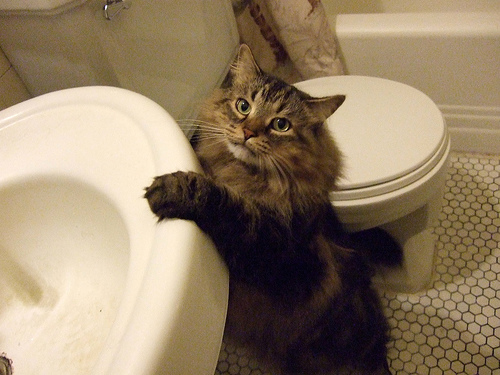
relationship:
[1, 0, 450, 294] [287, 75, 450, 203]
toilet has seat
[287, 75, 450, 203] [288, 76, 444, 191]
seat has cover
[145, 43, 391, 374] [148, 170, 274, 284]
cat has paw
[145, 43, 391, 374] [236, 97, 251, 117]
cat has eye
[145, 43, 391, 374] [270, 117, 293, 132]
cat has eye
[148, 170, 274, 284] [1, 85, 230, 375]
paw on sink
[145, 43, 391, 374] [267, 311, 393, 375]
cat has back legs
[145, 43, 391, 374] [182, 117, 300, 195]
cat has whiskers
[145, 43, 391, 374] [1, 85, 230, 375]
cat next to sink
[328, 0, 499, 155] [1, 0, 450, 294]
bathtub behind toilet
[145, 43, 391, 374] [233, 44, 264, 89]
cat has ear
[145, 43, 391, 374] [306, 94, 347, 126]
cat has ear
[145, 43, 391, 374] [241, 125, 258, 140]
cat has nose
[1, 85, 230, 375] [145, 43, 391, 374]
sink near cat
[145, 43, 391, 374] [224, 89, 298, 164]
cat has face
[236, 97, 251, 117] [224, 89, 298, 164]
eye on face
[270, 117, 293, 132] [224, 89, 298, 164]
eye on face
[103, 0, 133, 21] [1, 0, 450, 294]
flush handle on toilet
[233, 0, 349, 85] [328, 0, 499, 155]
shower curtain near bathtub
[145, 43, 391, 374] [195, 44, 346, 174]
cat has head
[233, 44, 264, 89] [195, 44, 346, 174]
ear on head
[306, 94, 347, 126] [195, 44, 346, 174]
ear on head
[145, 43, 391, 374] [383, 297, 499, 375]
cat has shadow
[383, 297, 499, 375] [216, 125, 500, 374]
shadow on floor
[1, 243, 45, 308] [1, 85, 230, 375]
shadow inside sink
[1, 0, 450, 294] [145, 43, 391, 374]
toilet behind cat